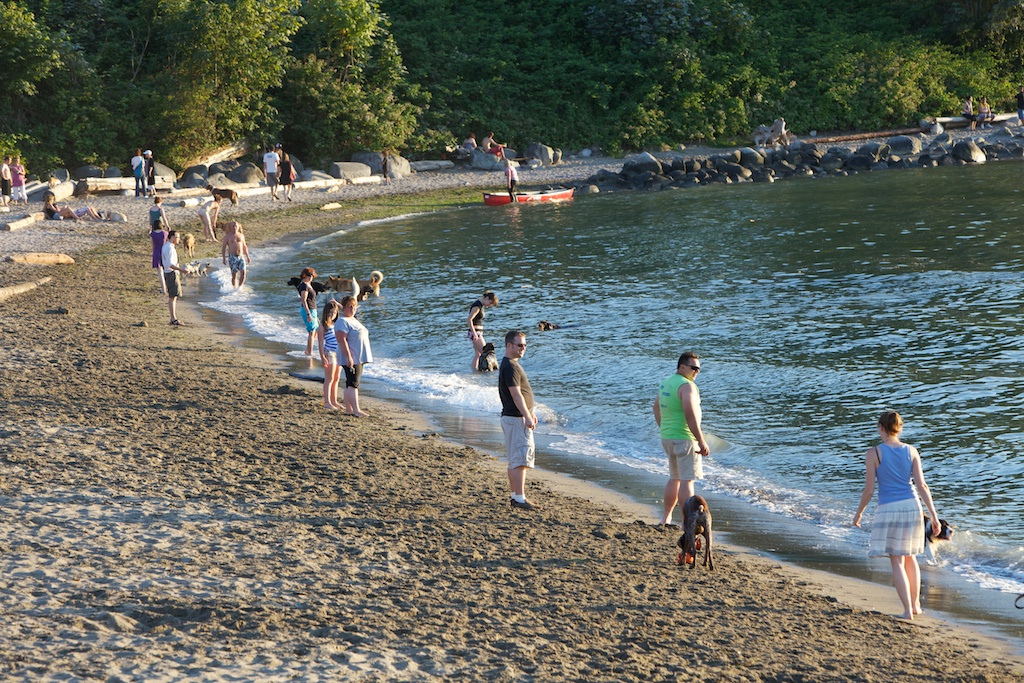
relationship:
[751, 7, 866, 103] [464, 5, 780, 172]
leaves on tree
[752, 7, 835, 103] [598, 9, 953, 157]
leaves on tree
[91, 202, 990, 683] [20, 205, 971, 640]
people are enjoying outdoors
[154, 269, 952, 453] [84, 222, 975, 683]
people are enjoying outdoors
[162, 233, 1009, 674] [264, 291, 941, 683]
people are enjoying outdoors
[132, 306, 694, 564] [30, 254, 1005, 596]
people are enjoying outdoors